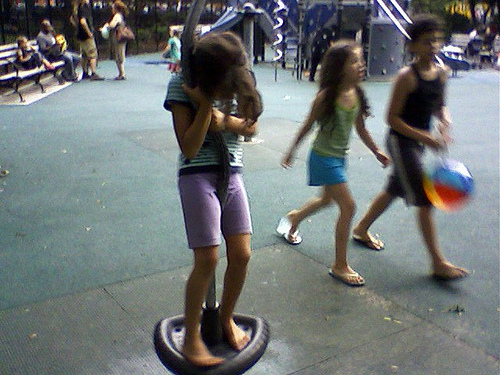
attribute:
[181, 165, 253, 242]
shorts — purple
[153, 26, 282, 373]
girl — small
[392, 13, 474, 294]
boy — small, walking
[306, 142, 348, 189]
shorts — blue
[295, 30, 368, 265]
girl — small, walking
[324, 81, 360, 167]
shirt — green, striped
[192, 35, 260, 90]
hair — brown, curly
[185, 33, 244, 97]
head — down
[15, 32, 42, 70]
person — sitting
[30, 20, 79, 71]
person — sitting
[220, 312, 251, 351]
foot — bare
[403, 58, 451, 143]
tank top — black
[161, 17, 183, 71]
kid — playing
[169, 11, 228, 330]
pole — black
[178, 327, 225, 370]
foot — bare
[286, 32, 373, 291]
kid — walking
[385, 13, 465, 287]
kid — walking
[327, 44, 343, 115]
hair — long